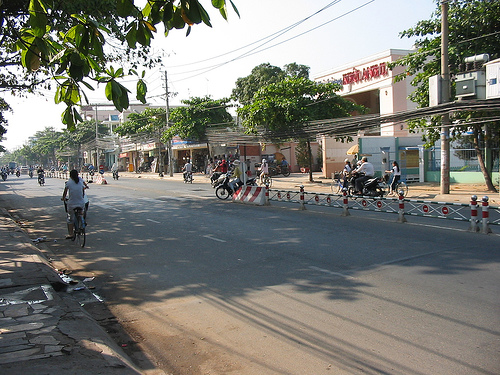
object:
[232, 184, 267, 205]
block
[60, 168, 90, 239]
person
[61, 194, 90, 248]
bike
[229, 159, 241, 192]
person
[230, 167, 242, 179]
shirt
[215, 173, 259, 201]
moped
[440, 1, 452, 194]
pole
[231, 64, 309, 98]
tree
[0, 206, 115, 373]
pavement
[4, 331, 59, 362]
stone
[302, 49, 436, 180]
building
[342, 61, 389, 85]
sign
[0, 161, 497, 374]
street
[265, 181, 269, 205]
caution pole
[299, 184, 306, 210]
caution pole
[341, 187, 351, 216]
caution pole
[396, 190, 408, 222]
caution pole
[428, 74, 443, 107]
electrical box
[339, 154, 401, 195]
group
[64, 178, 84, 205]
shirt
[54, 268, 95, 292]
garbage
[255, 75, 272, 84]
leaves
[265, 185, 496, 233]
safety railing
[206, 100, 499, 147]
electrical wires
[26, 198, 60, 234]
shadows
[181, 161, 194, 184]
man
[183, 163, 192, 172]
shirt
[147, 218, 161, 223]
line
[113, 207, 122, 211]
line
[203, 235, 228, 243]
line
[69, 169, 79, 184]
hair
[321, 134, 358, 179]
wall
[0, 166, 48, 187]
cyclists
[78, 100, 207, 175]
stores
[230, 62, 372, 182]
tree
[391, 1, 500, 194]
tree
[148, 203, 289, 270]
shadow